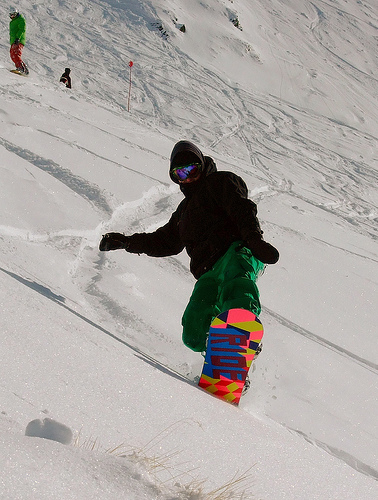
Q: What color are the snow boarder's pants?
A: Green.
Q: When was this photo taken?
A: During daytime.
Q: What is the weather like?
A: Bright and sunny.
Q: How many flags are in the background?
A: One.